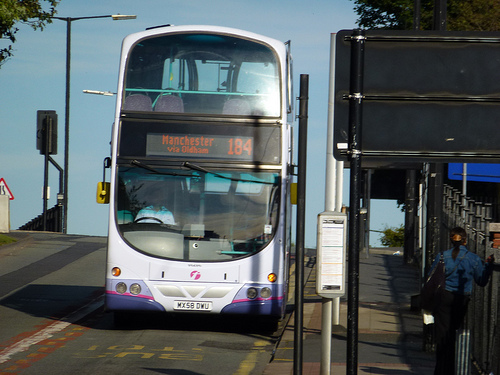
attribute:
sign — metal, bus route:
[302, 175, 397, 328]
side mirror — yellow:
[93, 184, 107, 201]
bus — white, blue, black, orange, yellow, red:
[88, 28, 297, 344]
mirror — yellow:
[94, 178, 111, 205]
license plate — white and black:
[171, 298, 216, 315]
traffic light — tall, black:
[30, 105, 58, 161]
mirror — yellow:
[95, 157, 113, 204]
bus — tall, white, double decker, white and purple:
[104, 16, 294, 318]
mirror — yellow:
[93, 180, 113, 209]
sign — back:
[332, 29, 499, 170]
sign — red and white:
[0, 176, 18, 204]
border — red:
[0, 175, 17, 201]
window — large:
[114, 158, 282, 262]